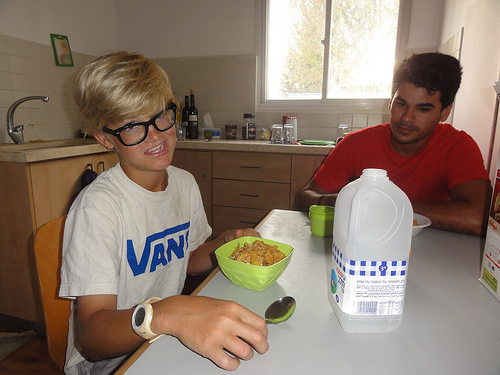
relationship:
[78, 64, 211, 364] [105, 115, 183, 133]
boy in glasses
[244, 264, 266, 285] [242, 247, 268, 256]
bowl with cereal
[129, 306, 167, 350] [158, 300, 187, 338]
watch on wrist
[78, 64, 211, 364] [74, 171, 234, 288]
boy wearing shirt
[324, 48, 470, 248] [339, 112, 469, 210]
man in shirt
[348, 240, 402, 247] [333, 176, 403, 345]
milk in carton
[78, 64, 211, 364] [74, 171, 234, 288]
boy in shirt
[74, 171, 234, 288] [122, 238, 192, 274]
shirt has letters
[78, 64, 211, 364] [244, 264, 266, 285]
boy has bowl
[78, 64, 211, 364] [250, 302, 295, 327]
boy with spoon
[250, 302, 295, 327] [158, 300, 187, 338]
spoon under wrist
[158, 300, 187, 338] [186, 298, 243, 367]
wrist on right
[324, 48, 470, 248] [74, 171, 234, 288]
man in shirt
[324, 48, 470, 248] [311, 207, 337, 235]
man has cup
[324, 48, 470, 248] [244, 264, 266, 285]
man has bowl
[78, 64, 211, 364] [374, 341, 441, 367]
boy at table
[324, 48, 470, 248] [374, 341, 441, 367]
man at table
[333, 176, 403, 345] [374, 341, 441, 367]
carton on table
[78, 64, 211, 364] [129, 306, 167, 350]
boy wearing watch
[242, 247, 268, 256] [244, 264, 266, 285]
cereal in bowl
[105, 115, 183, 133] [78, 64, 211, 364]
glasses on boy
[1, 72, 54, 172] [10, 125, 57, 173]
faucet on sink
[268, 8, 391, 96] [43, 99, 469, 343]
window in kitchen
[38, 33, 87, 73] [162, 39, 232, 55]
picture on wall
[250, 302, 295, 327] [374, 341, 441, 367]
spoon on table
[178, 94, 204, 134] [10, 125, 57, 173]
bottles on sink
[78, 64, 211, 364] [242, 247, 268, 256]
boy eating cereal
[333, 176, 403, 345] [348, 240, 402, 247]
carton for milk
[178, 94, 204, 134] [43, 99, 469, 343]
bottles in kitchen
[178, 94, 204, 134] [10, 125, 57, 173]
bottles by sink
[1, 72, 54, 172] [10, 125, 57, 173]
faucet over sink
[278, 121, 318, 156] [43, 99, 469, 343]
glasses in kitchen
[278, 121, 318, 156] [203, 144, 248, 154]
glasses on counter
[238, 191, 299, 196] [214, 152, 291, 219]
handle on cabinets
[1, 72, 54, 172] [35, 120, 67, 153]
faucet for water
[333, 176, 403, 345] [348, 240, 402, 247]
carton of milk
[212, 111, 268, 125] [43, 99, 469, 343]
jars in kitchen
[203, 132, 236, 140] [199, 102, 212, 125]
box of tissues